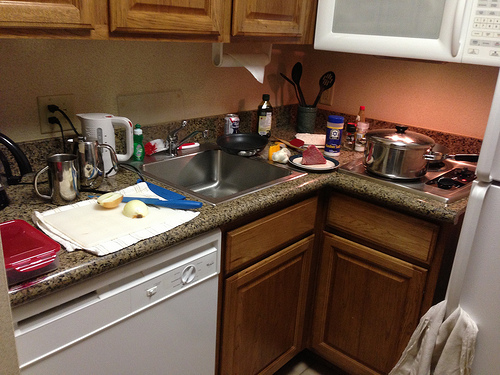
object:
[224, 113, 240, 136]
soda can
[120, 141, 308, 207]
sink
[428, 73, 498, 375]
refrigerator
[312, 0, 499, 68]
microwave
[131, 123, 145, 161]
bottle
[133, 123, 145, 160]
soap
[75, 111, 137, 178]
pitcher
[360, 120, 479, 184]
pot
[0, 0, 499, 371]
kitchen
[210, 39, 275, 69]
holder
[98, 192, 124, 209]
onion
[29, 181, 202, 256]
towle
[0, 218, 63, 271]
lid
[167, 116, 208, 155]
faucet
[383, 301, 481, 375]
towel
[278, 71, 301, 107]
utensils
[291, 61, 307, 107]
utensils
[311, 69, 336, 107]
utensils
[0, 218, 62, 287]
bowl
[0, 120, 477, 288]
countertop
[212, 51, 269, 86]
paper towel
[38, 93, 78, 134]
outlet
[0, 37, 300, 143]
wall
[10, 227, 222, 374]
dish washer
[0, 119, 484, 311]
counter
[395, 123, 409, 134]
knob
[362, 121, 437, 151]
lid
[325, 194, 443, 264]
drawer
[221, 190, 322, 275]
drawer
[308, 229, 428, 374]
door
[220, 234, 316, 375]
door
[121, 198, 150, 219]
onion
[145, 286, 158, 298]
switch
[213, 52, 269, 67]
roll